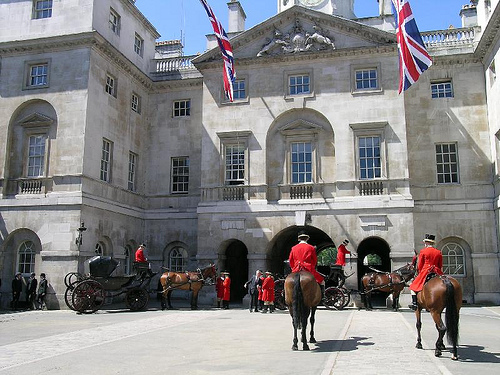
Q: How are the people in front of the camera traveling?
A: Horse.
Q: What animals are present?
A: Horses.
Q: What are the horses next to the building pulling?
A: Carriages.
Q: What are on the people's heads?
A: Hats.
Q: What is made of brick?
A: Building.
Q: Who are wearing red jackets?
A: Riders.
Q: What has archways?
A: Building.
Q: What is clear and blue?
A: Sky.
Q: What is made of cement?
A: Driveway.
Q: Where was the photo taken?
A: Great Britain.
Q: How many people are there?
A: Ten.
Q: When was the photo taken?
A: During the day.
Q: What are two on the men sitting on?
A: Horses.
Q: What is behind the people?
A: A building.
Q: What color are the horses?
A: Brown.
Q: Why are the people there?
A: To go for a ride.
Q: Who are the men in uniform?
A: Guards.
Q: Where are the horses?
A: In front of the building.